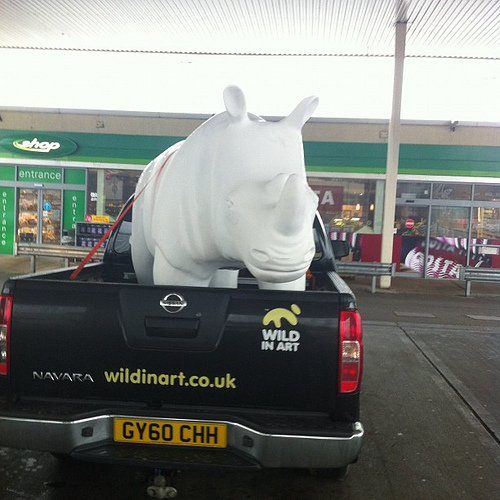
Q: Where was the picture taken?
A: It was taken at the store.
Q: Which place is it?
A: It is a store.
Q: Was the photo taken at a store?
A: Yes, it was taken in a store.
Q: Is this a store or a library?
A: It is a store.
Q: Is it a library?
A: No, it is a store.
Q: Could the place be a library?
A: No, it is a store.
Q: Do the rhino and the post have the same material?
A: No, the rhino is made of plastic and the post is made of metal.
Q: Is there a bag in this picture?
A: No, there are no bags.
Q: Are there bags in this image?
A: No, there are no bags.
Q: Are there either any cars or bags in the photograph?
A: No, there are no bags or cars.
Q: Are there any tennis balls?
A: No, there are no tennis balls.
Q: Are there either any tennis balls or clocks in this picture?
A: No, there are no tennis balls or clocks.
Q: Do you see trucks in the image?
A: Yes, there is a truck.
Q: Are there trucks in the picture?
A: Yes, there is a truck.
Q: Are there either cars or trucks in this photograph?
A: Yes, there is a truck.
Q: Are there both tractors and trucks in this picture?
A: No, there is a truck but no tractors.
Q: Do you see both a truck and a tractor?
A: No, there is a truck but no tractors.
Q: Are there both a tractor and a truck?
A: No, there is a truck but no tractors.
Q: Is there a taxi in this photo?
A: No, there are no taxis.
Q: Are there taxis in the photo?
A: No, there are no taxis.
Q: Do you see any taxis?
A: No, there are no taxis.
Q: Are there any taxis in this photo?
A: No, there are no taxis.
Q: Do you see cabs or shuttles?
A: No, there are no cabs or shuttles.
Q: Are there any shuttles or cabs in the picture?
A: No, there are no cabs or shuttles.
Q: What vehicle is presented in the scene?
A: The vehicle is a truck.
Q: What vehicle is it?
A: The vehicle is a truck.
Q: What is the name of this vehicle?
A: This is a truck.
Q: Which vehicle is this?
A: This is a truck.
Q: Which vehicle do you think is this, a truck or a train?
A: This is a truck.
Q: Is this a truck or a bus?
A: This is a truck.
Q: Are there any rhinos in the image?
A: Yes, there is a rhino.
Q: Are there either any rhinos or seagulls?
A: Yes, there is a rhino.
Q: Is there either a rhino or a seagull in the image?
A: Yes, there is a rhino.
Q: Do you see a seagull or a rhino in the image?
A: Yes, there is a rhino.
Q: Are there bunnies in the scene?
A: No, there are no bunnies.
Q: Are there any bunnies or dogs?
A: No, there are no bunnies or dogs.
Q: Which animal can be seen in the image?
A: The animal is a rhino.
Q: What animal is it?
A: The animal is a rhino.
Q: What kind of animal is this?
A: This is a rhino.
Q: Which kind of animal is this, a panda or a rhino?
A: This is a rhino.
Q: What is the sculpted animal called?
A: The animal is a rhino.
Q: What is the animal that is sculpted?
A: The animal is a rhino.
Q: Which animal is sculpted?
A: The animal is a rhino.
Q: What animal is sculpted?
A: The animal is a rhino.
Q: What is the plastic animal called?
A: The animal is a rhino.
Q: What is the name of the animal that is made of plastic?
A: The animal is a rhino.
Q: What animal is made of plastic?
A: The animal is a rhino.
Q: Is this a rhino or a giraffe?
A: This is a rhino.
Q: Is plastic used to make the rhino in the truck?
A: Yes, the rhino is made of plastic.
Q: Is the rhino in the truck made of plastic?
A: Yes, the rhino is made of plastic.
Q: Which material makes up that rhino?
A: The rhino is made of plastic.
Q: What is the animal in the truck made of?
A: The rhino is made of plastic.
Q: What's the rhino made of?
A: The rhino is made of plastic.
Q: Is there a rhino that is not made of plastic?
A: No, there is a rhino but it is made of plastic.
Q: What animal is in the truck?
A: The rhino is in the truck.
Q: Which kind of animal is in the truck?
A: The animal is a rhino.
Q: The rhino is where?
A: The rhino is in the truck.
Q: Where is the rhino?
A: The rhino is in the truck.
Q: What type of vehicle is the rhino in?
A: The rhino is in the truck.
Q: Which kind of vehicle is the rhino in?
A: The rhino is in the truck.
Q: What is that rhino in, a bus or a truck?
A: The rhino is in a truck.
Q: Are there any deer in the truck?
A: No, there is a rhino in the truck.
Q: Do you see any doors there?
A: Yes, there is a door.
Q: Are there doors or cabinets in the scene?
A: Yes, there is a door.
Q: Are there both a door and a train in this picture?
A: No, there is a door but no trains.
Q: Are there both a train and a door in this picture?
A: No, there is a door but no trains.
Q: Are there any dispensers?
A: No, there are no dispensers.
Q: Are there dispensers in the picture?
A: No, there are no dispensers.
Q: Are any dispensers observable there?
A: No, there are no dispensers.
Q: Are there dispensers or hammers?
A: No, there are no dispensers or hammers.